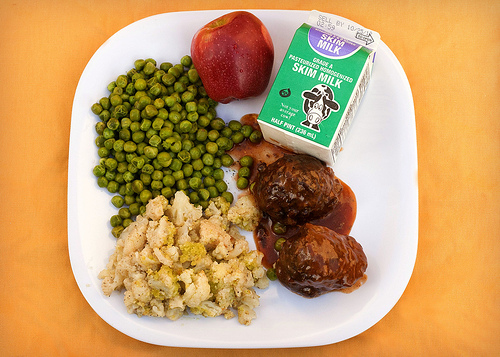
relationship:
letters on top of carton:
[288, 54, 354, 88] [256, 9, 381, 166]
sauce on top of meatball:
[321, 206, 355, 229] [277, 221, 366, 294]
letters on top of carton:
[285, 49, 354, 90] [256, 9, 381, 166]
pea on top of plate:
[185, 56, 192, 67] [65, 10, 424, 351]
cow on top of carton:
[297, 82, 342, 133] [256, 9, 381, 166]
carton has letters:
[256, 9, 381, 166] [288, 54, 354, 88]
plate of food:
[65, 10, 424, 351] [90, 11, 380, 325]